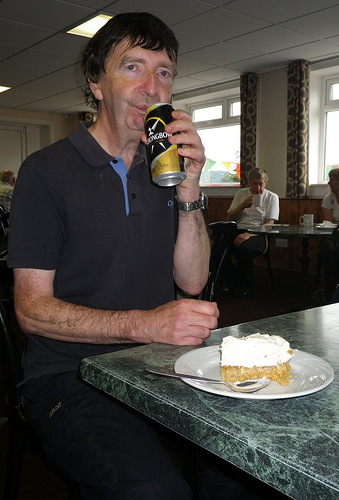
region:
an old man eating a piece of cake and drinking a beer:
[10, 41, 327, 400]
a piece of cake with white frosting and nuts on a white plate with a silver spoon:
[169, 331, 336, 407]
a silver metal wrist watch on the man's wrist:
[173, 188, 216, 214]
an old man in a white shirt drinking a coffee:
[222, 162, 281, 264]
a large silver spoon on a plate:
[142, 361, 272, 398]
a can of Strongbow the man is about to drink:
[133, 99, 186, 188]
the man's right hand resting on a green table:
[118, 296, 222, 348]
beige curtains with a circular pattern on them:
[283, 58, 316, 208]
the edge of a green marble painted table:
[79, 356, 171, 420]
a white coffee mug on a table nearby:
[299, 212, 315, 226]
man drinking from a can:
[16, 4, 223, 280]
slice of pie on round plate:
[152, 322, 338, 429]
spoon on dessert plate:
[134, 357, 270, 404]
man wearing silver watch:
[172, 176, 224, 235]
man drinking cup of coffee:
[223, 164, 286, 267]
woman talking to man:
[300, 161, 338, 245]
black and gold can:
[139, 96, 195, 196]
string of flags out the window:
[205, 149, 243, 178]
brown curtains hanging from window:
[228, 69, 314, 207]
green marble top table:
[76, 308, 332, 488]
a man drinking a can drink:
[24, 4, 276, 335]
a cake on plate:
[124, 284, 338, 437]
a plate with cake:
[139, 285, 336, 449]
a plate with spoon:
[146, 281, 326, 457]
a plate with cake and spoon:
[132, 268, 324, 437]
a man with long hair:
[11, 6, 262, 325]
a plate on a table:
[97, 316, 338, 481]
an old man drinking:
[213, 133, 291, 265]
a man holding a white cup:
[235, 143, 308, 279]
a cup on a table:
[269, 179, 329, 256]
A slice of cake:
[233, 325, 311, 388]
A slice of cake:
[192, 351, 261, 433]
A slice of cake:
[213, 300, 271, 434]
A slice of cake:
[234, 362, 294, 423]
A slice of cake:
[226, 328, 291, 498]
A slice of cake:
[236, 306, 285, 446]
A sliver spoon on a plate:
[136, 364, 277, 404]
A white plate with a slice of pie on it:
[169, 330, 336, 420]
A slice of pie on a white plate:
[215, 328, 296, 389]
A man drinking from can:
[15, 11, 225, 371]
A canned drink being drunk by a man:
[140, 100, 191, 190]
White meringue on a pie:
[218, 327, 295, 367]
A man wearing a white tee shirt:
[228, 163, 283, 242]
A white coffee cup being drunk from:
[250, 191, 265, 209]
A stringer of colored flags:
[203, 156, 242, 176]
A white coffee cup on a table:
[295, 211, 319, 236]